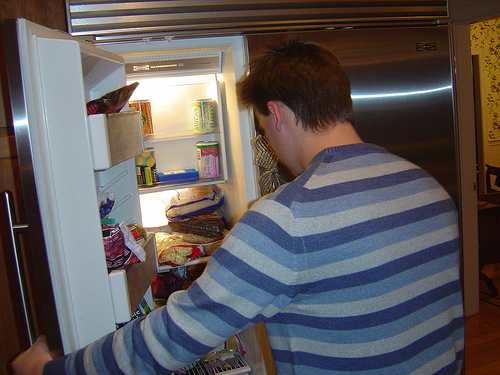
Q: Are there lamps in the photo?
A: No, there are no lamps.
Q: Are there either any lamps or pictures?
A: No, there are no lamps or pictures.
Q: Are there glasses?
A: No, there are no glasses.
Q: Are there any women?
A: No, there are no women.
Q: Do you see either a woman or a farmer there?
A: No, there are no women or farmers.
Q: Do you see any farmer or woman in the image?
A: No, there are no women or farmers.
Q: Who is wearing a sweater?
A: The boy is wearing a sweater.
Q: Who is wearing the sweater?
A: The boy is wearing a sweater.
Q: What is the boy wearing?
A: The boy is wearing a sweater.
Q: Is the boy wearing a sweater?
A: Yes, the boy is wearing a sweater.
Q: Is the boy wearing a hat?
A: No, the boy is wearing a sweater.